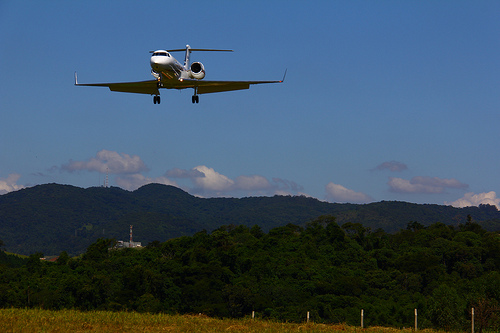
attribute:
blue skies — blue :
[351, 19, 497, 119]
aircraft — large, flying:
[66, 46, 288, 107]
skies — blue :
[4, 0, 499, 205]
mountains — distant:
[4, 181, 497, 250]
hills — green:
[0, 183, 499, 242]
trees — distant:
[4, 176, 499, 252]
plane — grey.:
[67, 40, 291, 109]